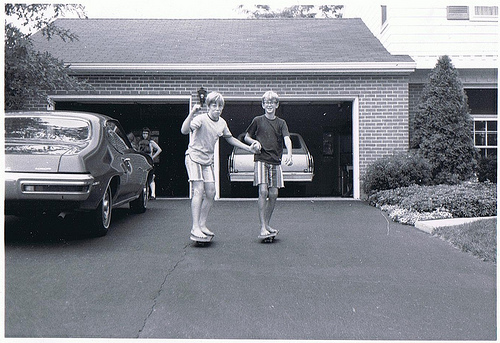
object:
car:
[228, 132, 315, 196]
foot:
[190, 228, 207, 238]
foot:
[200, 227, 216, 235]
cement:
[5, 201, 498, 341]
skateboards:
[190, 235, 214, 246]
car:
[0, 110, 156, 237]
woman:
[139, 127, 163, 200]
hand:
[150, 156, 154, 160]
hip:
[151, 155, 156, 163]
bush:
[410, 54, 480, 183]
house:
[7, 17, 498, 201]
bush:
[363, 152, 433, 192]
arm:
[222, 120, 249, 152]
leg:
[252, 162, 268, 229]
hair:
[206, 92, 225, 108]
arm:
[244, 116, 258, 143]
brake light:
[23, 184, 90, 193]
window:
[472, 120, 497, 146]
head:
[205, 91, 225, 119]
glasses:
[263, 100, 278, 104]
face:
[263, 97, 276, 113]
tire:
[80, 183, 112, 237]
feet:
[260, 227, 270, 236]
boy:
[179, 90, 260, 239]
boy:
[244, 89, 293, 236]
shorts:
[253, 160, 286, 188]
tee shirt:
[246, 114, 290, 165]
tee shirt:
[184, 113, 232, 165]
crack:
[150, 246, 189, 326]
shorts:
[184, 154, 216, 183]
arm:
[178, 112, 201, 135]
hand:
[249, 146, 262, 154]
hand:
[284, 156, 294, 166]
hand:
[191, 103, 202, 112]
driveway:
[2, 193, 497, 338]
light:
[196, 87, 208, 106]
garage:
[0, 17, 418, 199]